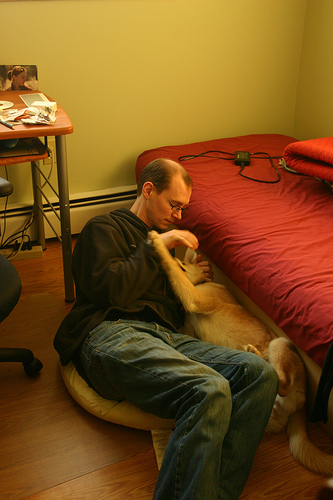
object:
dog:
[147, 229, 332, 487]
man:
[53, 157, 279, 499]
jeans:
[79, 318, 279, 498]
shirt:
[52, 206, 178, 364]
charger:
[178, 149, 284, 184]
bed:
[135, 132, 332, 443]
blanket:
[282, 137, 332, 182]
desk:
[0, 88, 77, 303]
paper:
[21, 100, 56, 125]